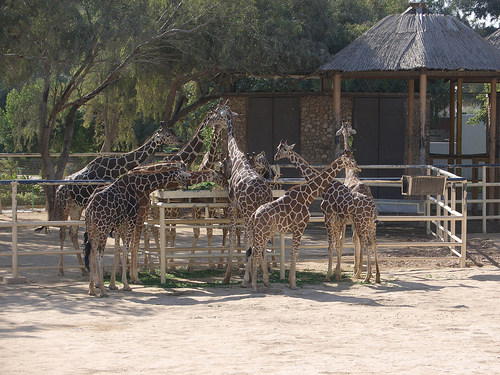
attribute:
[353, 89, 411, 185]
door — wooden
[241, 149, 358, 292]
giraffe — brown, white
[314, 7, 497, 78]
roof — grass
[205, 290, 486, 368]
sand — brown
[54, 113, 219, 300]
giraffe — white, brown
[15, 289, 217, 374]
sand — brown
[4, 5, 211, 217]
tree — tall, green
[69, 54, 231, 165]
plants — green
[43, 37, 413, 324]
giraffes — pack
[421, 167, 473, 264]
fence — white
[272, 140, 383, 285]
giraffe — young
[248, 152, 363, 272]
giraffe — young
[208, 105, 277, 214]
giraffe — young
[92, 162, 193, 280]
giraffe — young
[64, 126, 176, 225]
giraffe — young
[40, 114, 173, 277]
giraffes — brown, white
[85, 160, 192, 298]
giraffes — brown, white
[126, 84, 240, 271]
giraffes — brown, white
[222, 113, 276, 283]
giraffes — brown, white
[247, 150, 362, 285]
giraffes — brown, white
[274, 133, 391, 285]
giraffes — brown, white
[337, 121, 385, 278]
giraffes — brown, white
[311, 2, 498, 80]
roof — thatched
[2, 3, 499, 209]
trees — on the left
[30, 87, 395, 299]
giraffes — grouped together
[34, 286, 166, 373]
ground — sand, brown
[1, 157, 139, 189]
paint — some, chipped